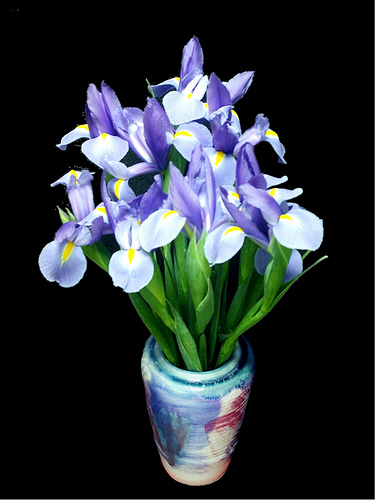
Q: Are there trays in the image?
A: No, there are no trays.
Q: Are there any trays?
A: No, there are no trays.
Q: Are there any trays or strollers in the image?
A: No, there are no trays or strollers.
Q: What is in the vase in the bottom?
A: The flower is in the vase.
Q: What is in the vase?
A: The flower is in the vase.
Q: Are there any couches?
A: No, there are no couches.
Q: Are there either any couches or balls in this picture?
A: No, there are no couches or balls.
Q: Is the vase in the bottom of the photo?
A: Yes, the vase is in the bottom of the image.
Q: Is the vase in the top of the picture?
A: No, the vase is in the bottom of the image.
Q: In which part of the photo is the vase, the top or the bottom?
A: The vase is in the bottom of the image.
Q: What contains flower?
A: The vase contains flower.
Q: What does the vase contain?
A: The vase contains flower.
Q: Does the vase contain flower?
A: Yes, the vase contains flower.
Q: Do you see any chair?
A: No, there are no chairs.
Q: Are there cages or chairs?
A: No, there are no chairs or cages.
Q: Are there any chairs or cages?
A: No, there are no chairs or cages.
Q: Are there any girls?
A: No, there are no girls.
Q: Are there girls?
A: No, there are no girls.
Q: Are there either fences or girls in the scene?
A: No, there are no girls or fences.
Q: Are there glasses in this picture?
A: No, there are no glasses.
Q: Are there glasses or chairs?
A: No, there are no glasses or chairs.